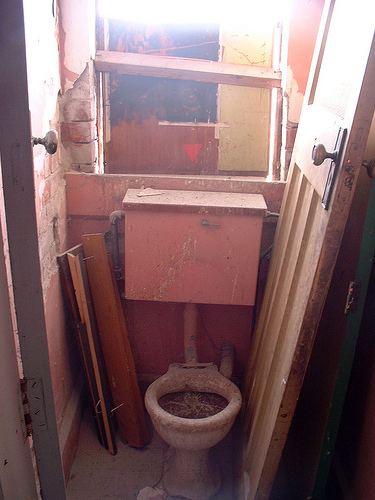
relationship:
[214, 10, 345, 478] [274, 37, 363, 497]
door leaning against wall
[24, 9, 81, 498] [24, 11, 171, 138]
brick wall with peeling paper peeling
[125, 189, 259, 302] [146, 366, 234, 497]
tank of toilet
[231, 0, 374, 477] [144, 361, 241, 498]
door by toilet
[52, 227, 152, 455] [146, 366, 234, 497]
wood by toilet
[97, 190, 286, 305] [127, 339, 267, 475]
tank above toilet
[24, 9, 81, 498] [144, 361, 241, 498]
brick wall by toilet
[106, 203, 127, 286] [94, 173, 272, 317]
pipe by tank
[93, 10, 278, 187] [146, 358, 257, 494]
window behind toilet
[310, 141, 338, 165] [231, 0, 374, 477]
door knob on door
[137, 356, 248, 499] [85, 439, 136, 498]
toilet on floor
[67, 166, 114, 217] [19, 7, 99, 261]
paint off wall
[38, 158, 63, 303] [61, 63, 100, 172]
paint peeling off paint peeling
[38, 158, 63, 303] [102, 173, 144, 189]
paint peeling off paint peeling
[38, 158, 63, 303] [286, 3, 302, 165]
paint peeling off peeling paint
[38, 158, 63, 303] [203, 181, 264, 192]
paint peeling off paint peeling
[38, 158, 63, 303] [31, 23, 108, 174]
paint peeling off wall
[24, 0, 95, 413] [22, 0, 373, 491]
peeling paint off wall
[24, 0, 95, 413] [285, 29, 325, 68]
peeling paint peeling wall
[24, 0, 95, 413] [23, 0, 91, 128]
peeling paint off wall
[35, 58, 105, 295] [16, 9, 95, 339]
exposed brick in wall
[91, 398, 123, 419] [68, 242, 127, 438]
mails in wood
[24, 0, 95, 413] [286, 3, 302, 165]
peeling paint on peeling paint